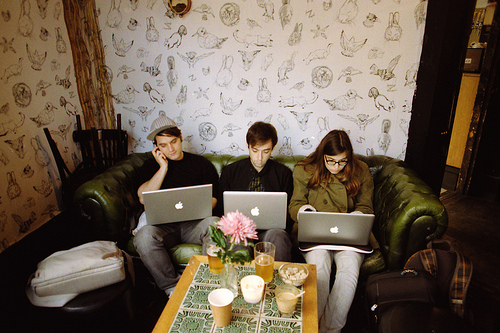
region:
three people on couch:
[141, 112, 372, 241]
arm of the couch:
[387, 167, 447, 246]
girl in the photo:
[273, 128, 377, 225]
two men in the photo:
[88, 98, 297, 238]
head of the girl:
[305, 133, 366, 188]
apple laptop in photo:
[222, 177, 294, 237]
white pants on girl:
[283, 246, 368, 318]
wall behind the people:
[179, 9, 334, 100]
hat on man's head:
[112, 103, 192, 170]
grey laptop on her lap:
[296, 210, 378, 250]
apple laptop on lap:
[223, 186, 297, 225]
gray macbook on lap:
[145, 187, 221, 220]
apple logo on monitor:
[172, 198, 187, 212]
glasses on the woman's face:
[327, 156, 345, 166]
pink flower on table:
[219, 211, 259, 243]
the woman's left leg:
[329, 249, 364, 331]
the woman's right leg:
[308, 244, 332, 312]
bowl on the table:
[276, 257, 309, 286]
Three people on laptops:
[20, 10, 448, 322]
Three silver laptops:
[141, 181, 371, 242]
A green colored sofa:
[73, 137, 435, 271]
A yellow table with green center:
[136, 242, 316, 332]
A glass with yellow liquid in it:
[247, 239, 276, 279]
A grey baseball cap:
[139, 109, 183, 151]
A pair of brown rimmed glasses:
[313, 142, 359, 179]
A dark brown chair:
[45, 107, 132, 171]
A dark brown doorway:
[421, 5, 473, 192]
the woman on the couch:
[278, 122, 387, 286]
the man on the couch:
[212, 113, 297, 255]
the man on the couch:
[119, 107, 221, 282]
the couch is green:
[86, 137, 461, 237]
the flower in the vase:
[172, 204, 261, 304]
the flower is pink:
[219, 209, 256, 241]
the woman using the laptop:
[278, 120, 387, 325]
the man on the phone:
[124, 106, 234, 258]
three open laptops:
[135, 179, 380, 258]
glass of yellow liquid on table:
[243, 236, 277, 291]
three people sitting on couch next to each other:
[130, 105, 377, 332]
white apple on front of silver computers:
[321, 220, 346, 240]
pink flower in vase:
[203, 212, 265, 301]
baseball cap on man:
[141, 112, 181, 144]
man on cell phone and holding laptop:
[135, 117, 225, 297]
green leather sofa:
[66, 144, 456, 279]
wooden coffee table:
[146, 246, 323, 332]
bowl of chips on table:
[277, 257, 312, 289]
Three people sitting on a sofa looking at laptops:
[130, 117, 380, 330]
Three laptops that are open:
[139, 181, 379, 246]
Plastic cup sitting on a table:
[206, 286, 237, 328]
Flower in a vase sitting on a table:
[216, 209, 260, 297]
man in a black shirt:
[125, 110, 222, 280]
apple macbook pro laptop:
[138, 178, 214, 221]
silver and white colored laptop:
[220, 178, 291, 236]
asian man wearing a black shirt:
[218, 117, 291, 232]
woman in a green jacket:
[286, 120, 372, 328]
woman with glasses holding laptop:
[296, 119, 373, 321]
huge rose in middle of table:
[205, 208, 259, 300]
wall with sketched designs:
[94, 5, 421, 162]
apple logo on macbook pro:
[249, 205, 259, 215]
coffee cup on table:
[206, 283, 235, 328]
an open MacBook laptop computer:
[138, 184, 213, 227]